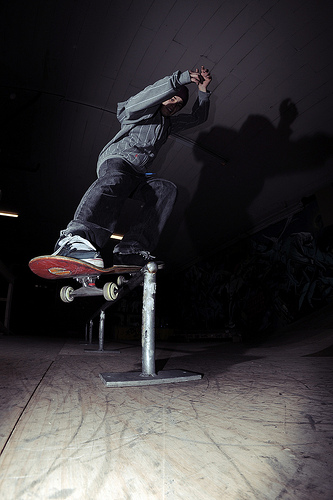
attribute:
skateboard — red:
[27, 252, 152, 300]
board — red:
[27, 251, 152, 305]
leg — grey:
[145, 264, 162, 379]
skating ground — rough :
[0, 335, 331, 498]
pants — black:
[56, 157, 183, 243]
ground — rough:
[17, 13, 312, 288]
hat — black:
[173, 84, 187, 102]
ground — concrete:
[53, 391, 267, 459]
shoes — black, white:
[46, 229, 163, 270]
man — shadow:
[54, 65, 214, 271]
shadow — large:
[190, 98, 332, 283]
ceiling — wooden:
[3, 4, 332, 246]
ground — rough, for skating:
[3, 336, 324, 498]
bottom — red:
[28, 255, 114, 278]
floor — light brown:
[6, 351, 331, 499]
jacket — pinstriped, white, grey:
[97, 70, 210, 169]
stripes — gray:
[94, 67, 212, 172]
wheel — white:
[101, 281, 122, 301]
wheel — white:
[59, 284, 75, 302]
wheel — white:
[115, 273, 128, 286]